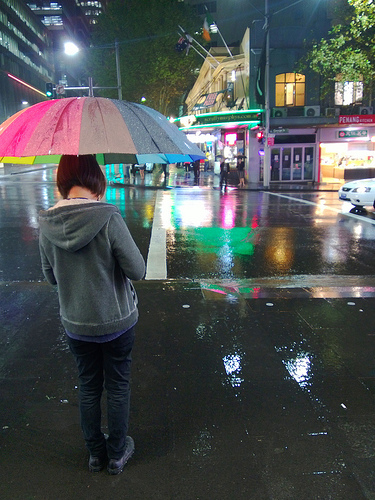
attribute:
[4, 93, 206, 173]
umbrella — colorful, wet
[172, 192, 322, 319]
street — wet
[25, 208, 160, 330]
jacket — gray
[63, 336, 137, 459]
pants — black, gray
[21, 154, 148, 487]
girl — standing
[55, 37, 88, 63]
light — white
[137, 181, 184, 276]
line — white